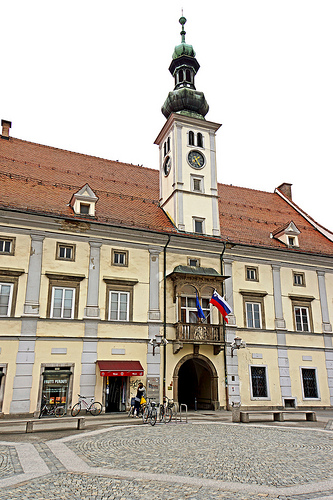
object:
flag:
[209, 290, 233, 324]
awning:
[96, 360, 143, 377]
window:
[109, 290, 129, 321]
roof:
[2, 158, 162, 218]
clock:
[186, 148, 207, 171]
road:
[0, 423, 332, 493]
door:
[101, 377, 129, 412]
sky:
[1, 5, 83, 68]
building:
[0, 76, 333, 418]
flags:
[187, 291, 243, 323]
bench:
[230, 403, 317, 423]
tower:
[153, 3, 225, 236]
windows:
[188, 131, 195, 146]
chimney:
[0, 118, 12, 139]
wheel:
[150, 408, 157, 427]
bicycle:
[142, 401, 158, 427]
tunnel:
[170, 353, 218, 412]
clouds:
[251, 48, 304, 104]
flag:
[196, 292, 206, 322]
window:
[68, 179, 99, 216]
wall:
[1, 231, 31, 401]